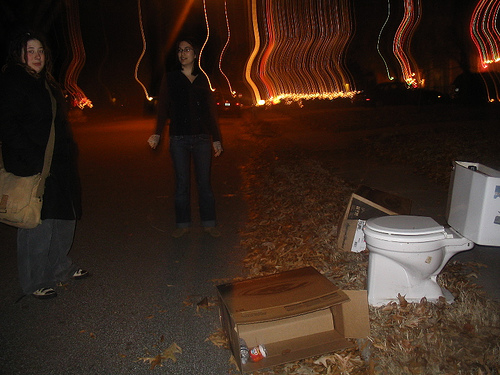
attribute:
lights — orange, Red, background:
[59, 0, 497, 110]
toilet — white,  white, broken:
[360, 156, 498, 309]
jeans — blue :
[164, 146, 195, 237]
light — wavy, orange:
[233, 10, 497, 88]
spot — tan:
[425, 251, 436, 279]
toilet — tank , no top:
[450, 148, 498, 238]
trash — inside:
[237, 335, 277, 373]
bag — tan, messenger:
[0, 71, 59, 226]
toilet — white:
[312, 154, 499, 308]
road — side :
[92, 242, 192, 303]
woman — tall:
[10, 28, 107, 316]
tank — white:
[448, 160, 499, 246]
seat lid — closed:
[345, 172, 450, 250]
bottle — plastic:
[235, 338, 247, 370]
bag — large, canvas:
[4, 143, 64, 226]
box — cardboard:
[180, 262, 405, 370]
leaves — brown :
[380, 339, 456, 373]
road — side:
[74, 241, 171, 358]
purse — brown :
[3, 85, 63, 231]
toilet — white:
[357, 155, 467, 303]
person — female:
[4, 50, 81, 227]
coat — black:
[5, 70, 86, 221]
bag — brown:
[4, 162, 45, 225]